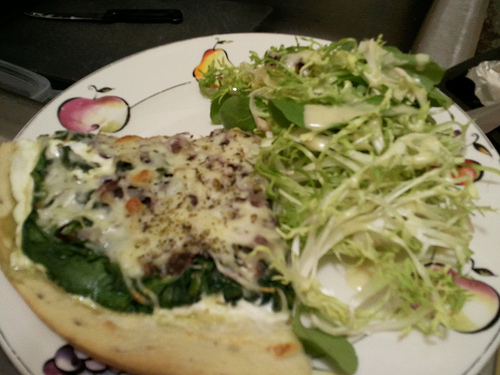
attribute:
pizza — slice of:
[1, 120, 308, 372]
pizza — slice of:
[13, 113, 407, 349]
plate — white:
[75, 44, 152, 92]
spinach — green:
[24, 225, 135, 318]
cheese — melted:
[106, 143, 253, 237]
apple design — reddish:
[53, 86, 138, 136]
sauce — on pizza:
[303, 100, 359, 146]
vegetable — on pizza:
[148, 51, 499, 346]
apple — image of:
[56, 82, 134, 139]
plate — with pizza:
[30, 20, 497, 332]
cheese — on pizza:
[43, 138, 283, 290]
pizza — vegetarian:
[12, 128, 283, 324]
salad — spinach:
[18, 26, 487, 373]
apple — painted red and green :
[52, 94, 133, 124]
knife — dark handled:
[21, 3, 188, 34]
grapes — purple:
[40, 343, 120, 373]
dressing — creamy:
[290, 113, 345, 156]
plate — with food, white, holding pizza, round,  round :
[3, 32, 499, 373]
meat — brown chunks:
[168, 137, 193, 162]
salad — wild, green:
[290, 123, 431, 247]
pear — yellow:
[192, 30, 242, 100]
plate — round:
[113, 74, 496, 296]